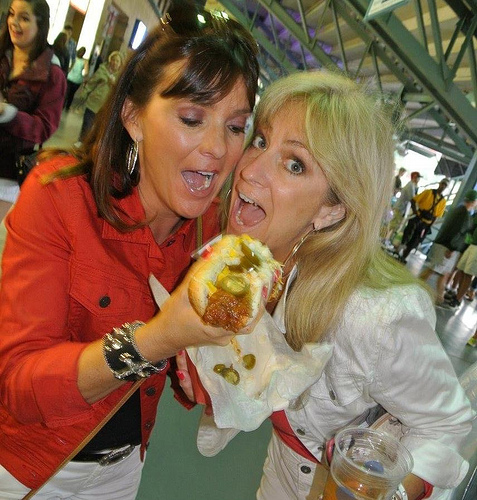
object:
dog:
[187, 231, 284, 333]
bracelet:
[100, 320, 167, 383]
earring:
[127, 139, 140, 176]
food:
[187, 232, 285, 333]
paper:
[184, 308, 335, 432]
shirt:
[414, 188, 446, 225]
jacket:
[0, 154, 229, 490]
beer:
[321, 464, 390, 499]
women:
[0, 9, 261, 498]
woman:
[175, 67, 476, 499]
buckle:
[70, 445, 136, 468]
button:
[300, 464, 312, 474]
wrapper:
[148, 272, 334, 432]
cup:
[321, 425, 414, 498]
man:
[417, 189, 476, 311]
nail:
[197, 246, 226, 267]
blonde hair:
[215, 64, 442, 352]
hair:
[24, 10, 261, 234]